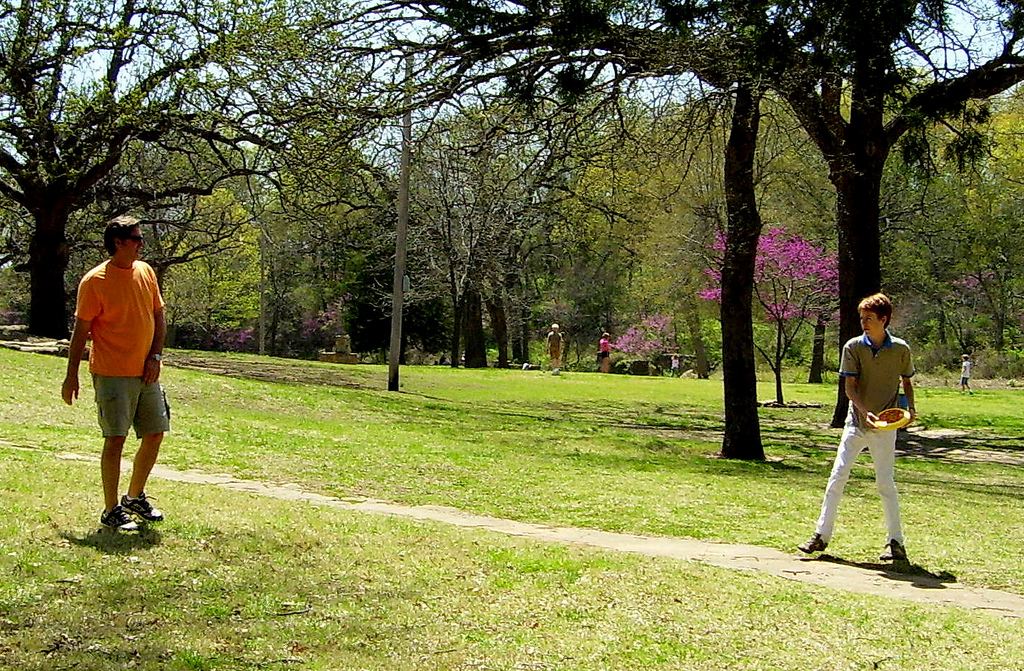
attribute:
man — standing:
[40, 223, 274, 507]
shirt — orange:
[51, 258, 235, 431]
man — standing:
[755, 262, 989, 576]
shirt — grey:
[817, 329, 978, 479]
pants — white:
[777, 435, 942, 591]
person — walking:
[476, 312, 574, 392]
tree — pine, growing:
[552, 290, 674, 407]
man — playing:
[59, 217, 202, 570]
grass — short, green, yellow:
[418, 543, 669, 658]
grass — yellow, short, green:
[619, 526, 810, 643]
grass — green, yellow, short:
[275, 486, 504, 608]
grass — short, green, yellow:
[435, 415, 749, 519]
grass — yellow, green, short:
[264, 348, 621, 526]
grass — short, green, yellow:
[552, 448, 732, 546]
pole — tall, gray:
[297, 106, 445, 446]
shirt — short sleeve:
[789, 320, 934, 431]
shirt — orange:
[35, 229, 191, 407]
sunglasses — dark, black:
[103, 240, 164, 258]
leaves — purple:
[685, 225, 811, 344]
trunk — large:
[829, 158, 909, 340]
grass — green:
[6, 314, 992, 650]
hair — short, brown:
[851, 284, 888, 321]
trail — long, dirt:
[11, 420, 992, 632]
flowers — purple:
[760, 232, 825, 308]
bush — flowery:
[609, 314, 694, 379]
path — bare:
[67, 439, 992, 628]